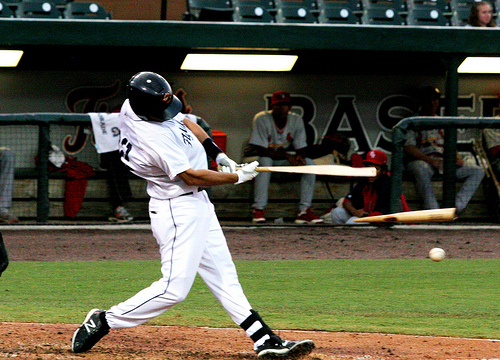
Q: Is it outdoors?
A: Yes, it is outdoors.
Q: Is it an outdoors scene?
A: Yes, it is outdoors.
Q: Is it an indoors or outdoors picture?
A: It is outdoors.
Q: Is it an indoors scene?
A: No, it is outdoors.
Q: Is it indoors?
A: No, it is outdoors.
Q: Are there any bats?
A: Yes, there is a bat.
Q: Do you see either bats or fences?
A: Yes, there is a bat.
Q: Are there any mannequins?
A: No, there are no mannequins.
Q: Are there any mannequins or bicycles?
A: No, there are no mannequins or bicycles.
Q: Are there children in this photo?
A: No, there are no children.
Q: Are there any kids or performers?
A: No, there are no kids or performers.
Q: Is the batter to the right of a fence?
A: Yes, the batter is to the right of a fence.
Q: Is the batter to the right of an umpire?
A: No, the batter is to the right of a fence.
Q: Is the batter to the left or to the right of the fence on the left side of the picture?
A: The batter is to the right of the fence.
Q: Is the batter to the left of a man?
A: Yes, the batter is to the left of a man.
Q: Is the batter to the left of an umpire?
A: No, the batter is to the left of a man.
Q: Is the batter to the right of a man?
A: No, the batter is to the left of a man.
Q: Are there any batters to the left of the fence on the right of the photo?
A: Yes, there is a batter to the left of the fence.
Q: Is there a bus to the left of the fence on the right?
A: No, there is a batter to the left of the fence.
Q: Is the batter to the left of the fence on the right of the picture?
A: Yes, the batter is to the left of the fence.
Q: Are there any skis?
A: No, there are no skis.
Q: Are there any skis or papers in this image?
A: No, there are no skis or papers.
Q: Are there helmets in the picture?
A: Yes, there is a helmet.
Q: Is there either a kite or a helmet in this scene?
A: Yes, there is a helmet.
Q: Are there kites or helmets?
A: Yes, there is a helmet.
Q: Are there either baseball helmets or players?
A: Yes, there is a baseball helmet.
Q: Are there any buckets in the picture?
A: No, there are no buckets.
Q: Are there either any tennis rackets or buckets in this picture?
A: No, there are no buckets or tennis rackets.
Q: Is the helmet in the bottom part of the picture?
A: No, the helmet is in the top of the image.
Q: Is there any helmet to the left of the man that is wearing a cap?
A: Yes, there is a helmet to the left of the man.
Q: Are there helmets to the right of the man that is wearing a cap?
A: No, the helmet is to the left of the man.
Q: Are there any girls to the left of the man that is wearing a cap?
A: No, there is a helmet to the left of the man.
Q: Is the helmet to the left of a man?
A: Yes, the helmet is to the left of a man.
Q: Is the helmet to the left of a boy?
A: No, the helmet is to the left of a man.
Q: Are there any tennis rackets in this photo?
A: No, there are no tennis rackets.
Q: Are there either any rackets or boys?
A: No, there are no rackets or boys.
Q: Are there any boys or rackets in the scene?
A: No, there are no rackets or boys.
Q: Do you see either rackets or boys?
A: No, there are no rackets or boys.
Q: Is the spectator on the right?
A: Yes, the spectator is on the right of the image.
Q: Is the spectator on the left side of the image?
A: No, the spectator is on the right of the image.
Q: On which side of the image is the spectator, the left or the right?
A: The spectator is on the right of the image.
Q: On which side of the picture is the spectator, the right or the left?
A: The spectator is on the right of the image.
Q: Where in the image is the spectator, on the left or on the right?
A: The spectator is on the right of the image.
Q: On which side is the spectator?
A: The spectator is on the right of the image.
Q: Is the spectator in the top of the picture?
A: Yes, the spectator is in the top of the image.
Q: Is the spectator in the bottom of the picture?
A: No, the spectator is in the top of the image.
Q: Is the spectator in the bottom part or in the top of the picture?
A: The spectator is in the top of the image.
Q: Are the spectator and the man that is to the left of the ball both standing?
A: Yes, both the spectator and the man are standing.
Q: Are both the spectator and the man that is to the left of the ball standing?
A: Yes, both the spectator and the man are standing.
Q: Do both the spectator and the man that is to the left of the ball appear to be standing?
A: Yes, both the spectator and the man are standing.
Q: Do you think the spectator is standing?
A: Yes, the spectator is standing.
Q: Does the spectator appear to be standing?
A: Yes, the spectator is standing.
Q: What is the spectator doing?
A: The spectator is standing.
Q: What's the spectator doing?
A: The spectator is standing.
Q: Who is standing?
A: The spectator is standing.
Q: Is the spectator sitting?
A: No, the spectator is standing.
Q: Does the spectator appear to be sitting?
A: No, the spectator is standing.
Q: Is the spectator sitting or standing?
A: The spectator is standing.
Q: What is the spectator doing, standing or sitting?
A: The spectator is standing.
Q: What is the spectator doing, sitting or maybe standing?
A: The spectator is standing.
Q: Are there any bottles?
A: No, there are no bottles.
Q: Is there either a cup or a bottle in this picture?
A: No, there are no bottles or cups.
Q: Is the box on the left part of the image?
A: Yes, the box is on the left of the image.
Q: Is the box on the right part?
A: No, the box is on the left of the image.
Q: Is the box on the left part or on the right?
A: The box is on the left of the image.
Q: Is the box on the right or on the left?
A: The box is on the left of the image.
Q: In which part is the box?
A: The box is on the left of the image.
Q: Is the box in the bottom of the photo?
A: Yes, the box is in the bottom of the image.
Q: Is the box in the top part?
A: No, the box is in the bottom of the image.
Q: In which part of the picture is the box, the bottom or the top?
A: The box is in the bottom of the image.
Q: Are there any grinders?
A: No, there are no grinders.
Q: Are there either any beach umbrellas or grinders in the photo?
A: No, there are no grinders or beach umbrellas.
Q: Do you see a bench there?
A: Yes, there is a bench.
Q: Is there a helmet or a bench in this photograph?
A: Yes, there is a bench.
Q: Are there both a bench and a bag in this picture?
A: No, there is a bench but no bags.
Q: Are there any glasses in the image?
A: No, there are no glasses.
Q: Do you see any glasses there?
A: No, there are no glasses.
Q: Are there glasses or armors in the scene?
A: No, there are no glasses or armors.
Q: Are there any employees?
A: No, there are no employees.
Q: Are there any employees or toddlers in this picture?
A: No, there are no employees or toddlers.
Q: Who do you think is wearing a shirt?
A: The man is wearing a shirt.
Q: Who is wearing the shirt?
A: The man is wearing a shirt.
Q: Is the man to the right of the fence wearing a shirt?
A: Yes, the man is wearing a shirt.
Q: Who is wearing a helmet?
A: The man is wearing a helmet.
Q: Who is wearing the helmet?
A: The man is wearing a helmet.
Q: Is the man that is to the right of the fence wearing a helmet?
A: Yes, the man is wearing a helmet.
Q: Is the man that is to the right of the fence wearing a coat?
A: No, the man is wearing a helmet.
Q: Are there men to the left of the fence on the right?
A: Yes, there is a man to the left of the fence.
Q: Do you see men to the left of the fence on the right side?
A: Yes, there is a man to the left of the fence.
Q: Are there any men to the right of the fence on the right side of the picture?
A: No, the man is to the left of the fence.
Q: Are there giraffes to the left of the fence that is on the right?
A: No, there is a man to the left of the fence.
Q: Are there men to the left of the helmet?
A: No, the man is to the right of the helmet.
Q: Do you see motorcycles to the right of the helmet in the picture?
A: No, there is a man to the right of the helmet.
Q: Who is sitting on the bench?
A: The man is sitting on the bench.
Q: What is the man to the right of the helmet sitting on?
A: The man is sitting on the bench.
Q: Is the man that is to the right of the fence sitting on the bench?
A: Yes, the man is sitting on the bench.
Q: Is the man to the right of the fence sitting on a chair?
A: No, the man is sitting on the bench.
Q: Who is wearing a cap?
A: The man is wearing a cap.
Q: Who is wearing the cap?
A: The man is wearing a cap.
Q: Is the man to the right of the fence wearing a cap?
A: Yes, the man is wearing a cap.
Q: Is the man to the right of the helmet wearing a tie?
A: No, the man is wearing a cap.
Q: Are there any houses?
A: No, there are no houses.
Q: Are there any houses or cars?
A: No, there are no houses or cars.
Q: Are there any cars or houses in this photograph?
A: No, there are no houses or cars.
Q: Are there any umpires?
A: No, there are no umpires.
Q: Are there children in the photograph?
A: No, there are no children.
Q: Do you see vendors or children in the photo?
A: No, there are no children or vendors.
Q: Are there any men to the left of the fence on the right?
A: Yes, there is a man to the left of the fence.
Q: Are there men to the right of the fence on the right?
A: No, the man is to the left of the fence.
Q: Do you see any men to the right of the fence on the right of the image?
A: No, the man is to the left of the fence.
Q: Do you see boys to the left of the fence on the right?
A: No, there is a man to the left of the fence.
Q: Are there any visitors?
A: No, there are no visitors.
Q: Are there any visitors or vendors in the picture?
A: No, there are no visitors or vendors.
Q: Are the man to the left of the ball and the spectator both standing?
A: Yes, both the man and the spectator are standing.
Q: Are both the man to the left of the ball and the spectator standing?
A: Yes, both the man and the spectator are standing.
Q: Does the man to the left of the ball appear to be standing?
A: Yes, the man is standing.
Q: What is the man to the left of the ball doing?
A: The man is standing.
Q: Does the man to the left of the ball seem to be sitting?
A: No, the man is standing.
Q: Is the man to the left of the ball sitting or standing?
A: The man is standing.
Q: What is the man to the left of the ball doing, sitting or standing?
A: The man is standing.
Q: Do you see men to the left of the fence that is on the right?
A: Yes, there is a man to the left of the fence.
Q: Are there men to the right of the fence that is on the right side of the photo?
A: No, the man is to the left of the fence.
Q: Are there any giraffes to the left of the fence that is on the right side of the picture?
A: No, there is a man to the left of the fence.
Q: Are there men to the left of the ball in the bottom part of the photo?
A: Yes, there is a man to the left of the ball.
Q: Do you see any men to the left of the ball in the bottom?
A: Yes, there is a man to the left of the ball.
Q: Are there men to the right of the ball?
A: No, the man is to the left of the ball.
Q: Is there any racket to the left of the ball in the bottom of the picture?
A: No, there is a man to the left of the ball.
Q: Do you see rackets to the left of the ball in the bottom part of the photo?
A: No, there is a man to the left of the ball.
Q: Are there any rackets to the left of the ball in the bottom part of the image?
A: No, there is a man to the left of the ball.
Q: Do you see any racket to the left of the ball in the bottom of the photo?
A: No, there is a man to the left of the ball.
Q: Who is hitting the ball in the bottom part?
A: The man is hitting the ball.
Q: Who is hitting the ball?
A: The man is hitting the ball.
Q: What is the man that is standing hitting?
A: The man is hitting the ball.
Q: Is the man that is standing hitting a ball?
A: Yes, the man is hitting a ball.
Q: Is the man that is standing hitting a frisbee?
A: No, the man is hitting a ball.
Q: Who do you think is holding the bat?
A: The man is holding the bat.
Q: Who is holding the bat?
A: The man is holding the bat.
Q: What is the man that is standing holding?
A: The man is holding the bat.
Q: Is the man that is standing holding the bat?
A: Yes, the man is holding the bat.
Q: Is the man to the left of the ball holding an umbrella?
A: No, the man is holding the bat.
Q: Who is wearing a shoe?
A: The man is wearing a shoe.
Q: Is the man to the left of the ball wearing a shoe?
A: Yes, the man is wearing a shoe.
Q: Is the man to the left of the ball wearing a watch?
A: No, the man is wearing a shoe.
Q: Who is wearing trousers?
A: The man is wearing trousers.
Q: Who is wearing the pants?
A: The man is wearing trousers.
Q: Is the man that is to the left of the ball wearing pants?
A: Yes, the man is wearing pants.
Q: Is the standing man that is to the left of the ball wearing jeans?
A: No, the man is wearing pants.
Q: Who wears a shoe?
A: The man wears a shoe.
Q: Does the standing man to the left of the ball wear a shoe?
A: Yes, the man wears a shoe.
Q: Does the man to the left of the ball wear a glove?
A: No, the man wears a shoe.